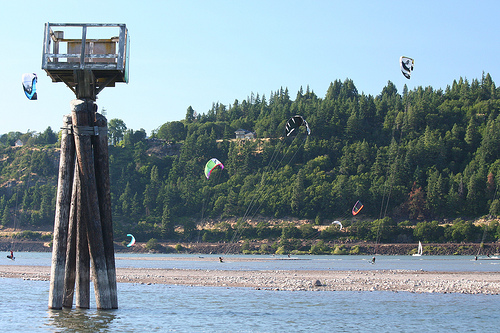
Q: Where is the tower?
A: On beach.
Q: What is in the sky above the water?
A: Windsurfing parachutes.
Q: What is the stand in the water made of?
A: Wood.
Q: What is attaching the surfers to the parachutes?
A: Ropes.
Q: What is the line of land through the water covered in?
A: Rock.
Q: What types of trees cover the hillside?
A: Evergreens.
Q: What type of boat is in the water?
A: A sailboat.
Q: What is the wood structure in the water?
A: A stand.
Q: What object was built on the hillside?
A: A house.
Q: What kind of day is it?
A: Sunny.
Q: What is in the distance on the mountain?
A: Trees.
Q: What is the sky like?
A: Clear.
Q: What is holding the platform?
A: Wooden poles.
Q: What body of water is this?
A: River.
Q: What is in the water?
A: Rocky ridge.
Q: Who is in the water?
A: Swimmers.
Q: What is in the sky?
A: Parachutes.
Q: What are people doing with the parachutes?
A: Parasailing.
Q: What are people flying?
A: Kites.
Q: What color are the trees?
A: Green.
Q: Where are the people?
A: In the water.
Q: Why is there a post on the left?
A: To mark the area.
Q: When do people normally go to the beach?
A: In the summer.